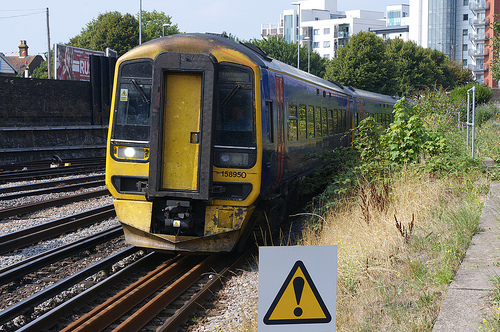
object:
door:
[155, 67, 204, 191]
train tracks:
[0, 203, 123, 280]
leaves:
[144, 10, 172, 27]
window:
[260, 99, 277, 146]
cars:
[342, 86, 396, 152]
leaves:
[330, 45, 375, 84]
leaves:
[487, 40, 500, 84]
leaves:
[392, 213, 404, 242]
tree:
[219, 29, 328, 79]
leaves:
[401, 55, 435, 89]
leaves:
[382, 118, 402, 162]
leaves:
[260, 38, 295, 62]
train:
[102, 33, 397, 255]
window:
[211, 60, 255, 147]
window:
[110, 77, 152, 142]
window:
[306, 105, 315, 140]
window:
[284, 99, 299, 143]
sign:
[257, 244, 337, 331]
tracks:
[0, 248, 245, 332]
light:
[121, 145, 137, 159]